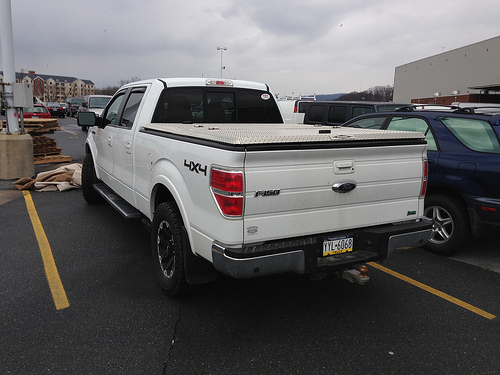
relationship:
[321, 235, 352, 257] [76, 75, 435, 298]
plate on truck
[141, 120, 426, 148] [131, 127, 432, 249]
cover for bed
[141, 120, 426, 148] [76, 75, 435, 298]
cover on truck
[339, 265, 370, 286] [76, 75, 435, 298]
hitch on truck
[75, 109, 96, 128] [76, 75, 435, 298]
mirror on truck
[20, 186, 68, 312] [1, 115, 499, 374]
lines on street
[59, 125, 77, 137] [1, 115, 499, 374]
lines on street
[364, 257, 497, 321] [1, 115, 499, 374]
lines on street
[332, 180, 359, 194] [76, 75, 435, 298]
emblem of truck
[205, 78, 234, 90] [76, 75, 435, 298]
light on truck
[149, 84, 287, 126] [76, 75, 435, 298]
window on truck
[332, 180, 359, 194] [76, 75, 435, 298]
emblem on truck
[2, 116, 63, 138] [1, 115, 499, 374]
pallets on street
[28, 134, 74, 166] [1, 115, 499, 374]
pallets on street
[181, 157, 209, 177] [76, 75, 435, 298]
4x4 on truck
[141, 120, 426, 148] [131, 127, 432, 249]
cover on bed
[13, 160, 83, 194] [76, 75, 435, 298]
tarp in front of truck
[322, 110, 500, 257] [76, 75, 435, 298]
car next to truck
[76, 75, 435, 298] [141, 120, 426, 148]
truck has cover